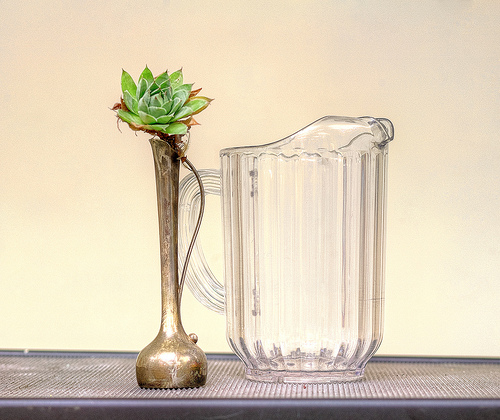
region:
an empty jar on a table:
[183, 110, 397, 385]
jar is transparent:
[185, 110, 400, 380]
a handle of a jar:
[182, 162, 227, 313]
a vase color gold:
[130, 132, 215, 388]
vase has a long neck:
[130, 135, 215, 390]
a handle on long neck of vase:
[130, 138, 211, 391]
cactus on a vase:
[102, 57, 217, 153]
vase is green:
[107, 55, 217, 145]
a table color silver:
[5, 346, 498, 416]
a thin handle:
[179, 146, 209, 301]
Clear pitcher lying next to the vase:
[177, 115, 392, 382]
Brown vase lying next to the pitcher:
[134, 138, 205, 398]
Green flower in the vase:
[112, 58, 210, 138]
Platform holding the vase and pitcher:
[0, 349, 498, 416]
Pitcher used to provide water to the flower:
[177, 113, 392, 385]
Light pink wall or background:
[1, 1, 498, 351]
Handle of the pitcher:
[172, 166, 227, 311]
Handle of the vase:
[178, 158, 205, 292]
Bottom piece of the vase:
[137, 336, 208, 387]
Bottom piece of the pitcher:
[244, 366, 371, 383]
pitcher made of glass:
[183, 80, 386, 415]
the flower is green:
[113, 71, 218, 148]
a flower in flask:
[97, 50, 212, 388]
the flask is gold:
[120, 140, 274, 407]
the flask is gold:
[138, 122, 213, 414]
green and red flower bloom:
[106, 66, 213, 146]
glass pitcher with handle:
[178, 103, 393, 383]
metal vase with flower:
[136, 133, 210, 391]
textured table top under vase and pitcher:
[1, 346, 498, 418]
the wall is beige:
[0, 0, 498, 357]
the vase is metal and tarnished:
[129, 137, 211, 393]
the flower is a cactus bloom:
[109, 63, 213, 145]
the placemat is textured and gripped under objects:
[1, 353, 498, 398]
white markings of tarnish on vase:
[134, 339, 208, 389]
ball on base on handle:
[190, 330, 199, 343]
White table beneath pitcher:
[56, 369, 108, 390]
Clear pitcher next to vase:
[184, 125, 391, 380]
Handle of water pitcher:
[182, 165, 219, 307]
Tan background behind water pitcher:
[66, 223, 110, 301]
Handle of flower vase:
[173, 155, 205, 305]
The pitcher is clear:
[280, 210, 323, 277]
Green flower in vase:
[118, 68, 206, 138]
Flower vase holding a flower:
[131, 138, 206, 390]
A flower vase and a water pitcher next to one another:
[107, 81, 392, 381]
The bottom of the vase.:
[135, 338, 207, 386]